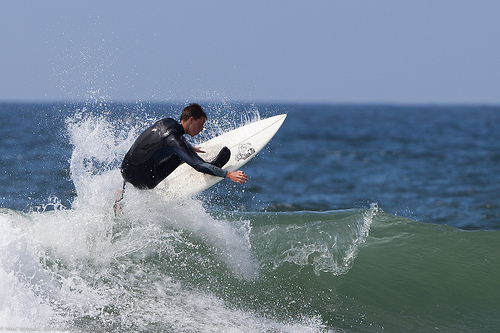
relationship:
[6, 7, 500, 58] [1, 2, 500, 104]
clouds in sky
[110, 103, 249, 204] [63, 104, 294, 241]
man on surfboard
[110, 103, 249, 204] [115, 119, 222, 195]
surfer has wetsuit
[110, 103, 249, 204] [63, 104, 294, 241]
surfer on surfboard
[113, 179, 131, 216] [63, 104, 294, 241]
cable on surfboard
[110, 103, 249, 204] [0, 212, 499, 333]
surfer riding wave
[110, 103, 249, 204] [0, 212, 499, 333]
surfer on wave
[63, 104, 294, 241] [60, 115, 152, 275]
surfboard creates splash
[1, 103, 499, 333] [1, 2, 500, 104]
ocean meets sky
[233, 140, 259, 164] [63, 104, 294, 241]
logo on surfboard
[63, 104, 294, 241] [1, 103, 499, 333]
surfboard on water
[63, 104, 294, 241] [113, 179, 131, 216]
surfboard has cable